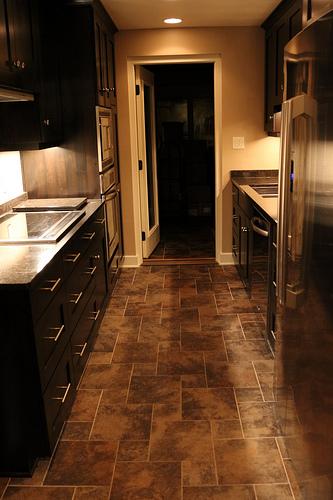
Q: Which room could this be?
A: It is a kitchen.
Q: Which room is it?
A: It is a kitchen.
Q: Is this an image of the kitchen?
A: Yes, it is showing the kitchen.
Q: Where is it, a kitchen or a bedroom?
A: It is a kitchen.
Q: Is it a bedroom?
A: No, it is a kitchen.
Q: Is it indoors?
A: Yes, it is indoors.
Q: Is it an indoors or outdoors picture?
A: It is indoors.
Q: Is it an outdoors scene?
A: No, it is indoors.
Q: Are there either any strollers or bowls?
A: No, there are no bowls or strollers.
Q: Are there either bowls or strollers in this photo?
A: No, there are no bowls or strollers.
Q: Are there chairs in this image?
A: No, there are no chairs.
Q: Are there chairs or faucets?
A: No, there are no chairs or faucets.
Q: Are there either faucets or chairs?
A: No, there are no chairs or faucets.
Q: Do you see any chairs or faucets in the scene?
A: No, there are no chairs or faucets.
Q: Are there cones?
A: No, there are no cones.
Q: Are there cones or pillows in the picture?
A: No, there are no cones or pillows.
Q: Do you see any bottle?
A: No, there are no bottles.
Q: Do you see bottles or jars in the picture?
A: No, there are no bottles or jars.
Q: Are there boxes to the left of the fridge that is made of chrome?
A: Yes, there are boxes to the left of the fridge.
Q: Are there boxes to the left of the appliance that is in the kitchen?
A: Yes, there are boxes to the left of the fridge.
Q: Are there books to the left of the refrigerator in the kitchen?
A: No, there are boxes to the left of the fridge.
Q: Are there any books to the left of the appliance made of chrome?
A: No, there are boxes to the left of the fridge.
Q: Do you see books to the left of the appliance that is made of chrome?
A: No, there are boxes to the left of the fridge.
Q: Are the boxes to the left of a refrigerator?
A: Yes, the boxes are to the left of a refrigerator.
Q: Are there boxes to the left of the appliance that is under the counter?
A: Yes, there are boxes to the left of the appliance.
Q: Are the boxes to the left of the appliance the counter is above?
A: Yes, the boxes are to the left of the appliance.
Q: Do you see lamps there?
A: No, there are no lamps.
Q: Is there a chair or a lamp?
A: No, there are no lamps or chairs.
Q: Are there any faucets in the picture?
A: No, there are no faucets.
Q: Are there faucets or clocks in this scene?
A: No, there are no faucets or clocks.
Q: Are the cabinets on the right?
A: No, the cabinets are on the left of the image.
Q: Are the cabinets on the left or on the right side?
A: The cabinets are on the left of the image.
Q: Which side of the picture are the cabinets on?
A: The cabinets are on the left of the image.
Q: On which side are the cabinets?
A: The cabinets are on the left of the image.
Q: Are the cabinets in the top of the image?
A: Yes, the cabinets are in the top of the image.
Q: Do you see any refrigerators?
A: Yes, there is a refrigerator.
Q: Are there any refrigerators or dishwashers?
A: Yes, there is a refrigerator.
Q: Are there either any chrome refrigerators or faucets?
A: Yes, there is a chrome refrigerator.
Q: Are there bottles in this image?
A: No, there are no bottles.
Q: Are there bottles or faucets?
A: No, there are no bottles or faucets.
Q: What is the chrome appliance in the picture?
A: The appliance is a refrigerator.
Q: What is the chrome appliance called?
A: The appliance is a refrigerator.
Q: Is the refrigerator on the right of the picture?
A: Yes, the refrigerator is on the right of the image.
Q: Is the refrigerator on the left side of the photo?
A: No, the refrigerator is on the right of the image.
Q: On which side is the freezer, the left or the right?
A: The freezer is on the right of the image.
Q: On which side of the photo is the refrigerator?
A: The refrigerator is on the right of the image.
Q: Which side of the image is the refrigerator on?
A: The refrigerator is on the right of the image.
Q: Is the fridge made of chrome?
A: Yes, the fridge is made of chrome.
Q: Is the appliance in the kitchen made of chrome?
A: Yes, the fridge is made of chrome.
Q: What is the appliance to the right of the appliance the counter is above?
A: The appliance is a refrigerator.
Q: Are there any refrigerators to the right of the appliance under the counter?
A: Yes, there is a refrigerator to the right of the appliance.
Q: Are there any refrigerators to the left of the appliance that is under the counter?
A: No, the refrigerator is to the right of the appliance.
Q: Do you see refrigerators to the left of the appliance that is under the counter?
A: No, the refrigerator is to the right of the appliance.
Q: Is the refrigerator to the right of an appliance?
A: Yes, the refrigerator is to the right of an appliance.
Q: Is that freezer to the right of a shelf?
A: No, the freezer is to the right of an appliance.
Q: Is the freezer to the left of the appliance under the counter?
A: No, the freezer is to the right of the appliance.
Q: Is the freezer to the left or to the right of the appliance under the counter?
A: The freezer is to the right of the appliance.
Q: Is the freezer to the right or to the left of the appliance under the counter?
A: The freezer is to the right of the appliance.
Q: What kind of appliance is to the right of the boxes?
A: The appliance is a refrigerator.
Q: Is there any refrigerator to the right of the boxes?
A: Yes, there is a refrigerator to the right of the boxes.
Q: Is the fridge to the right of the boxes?
A: Yes, the fridge is to the right of the boxes.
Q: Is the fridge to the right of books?
A: No, the fridge is to the right of the boxes.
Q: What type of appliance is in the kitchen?
A: The appliance is a refrigerator.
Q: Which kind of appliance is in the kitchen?
A: The appliance is a refrigerator.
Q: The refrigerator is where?
A: The refrigerator is in the kitchen.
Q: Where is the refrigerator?
A: The refrigerator is in the kitchen.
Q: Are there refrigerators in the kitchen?
A: Yes, there is a refrigerator in the kitchen.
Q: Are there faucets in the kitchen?
A: No, there is a refrigerator in the kitchen.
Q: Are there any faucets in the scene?
A: No, there are no faucets.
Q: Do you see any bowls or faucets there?
A: No, there are no faucets or bowls.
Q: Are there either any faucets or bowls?
A: No, there are no faucets or bowls.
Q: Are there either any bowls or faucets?
A: No, there are no faucets or bowls.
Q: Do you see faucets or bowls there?
A: No, there are no faucets or bowls.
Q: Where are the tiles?
A: The tiles are on the floor.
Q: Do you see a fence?
A: No, there are no fences.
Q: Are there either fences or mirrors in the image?
A: No, there are no fences or mirrors.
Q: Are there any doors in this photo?
A: Yes, there is a door.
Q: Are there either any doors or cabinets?
A: Yes, there is a door.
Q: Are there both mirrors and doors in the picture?
A: No, there is a door but no mirrors.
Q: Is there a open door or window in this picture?
A: Yes, there is an open door.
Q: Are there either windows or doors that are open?
A: Yes, the door is open.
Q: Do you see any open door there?
A: Yes, there is an open door.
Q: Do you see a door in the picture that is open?
A: Yes, there is a door that is open.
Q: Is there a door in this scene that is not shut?
A: Yes, there is a open door.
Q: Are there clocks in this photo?
A: No, there are no clocks.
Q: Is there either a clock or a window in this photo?
A: No, there are no clocks or windows.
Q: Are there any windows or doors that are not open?
A: No, there is a door but it is open.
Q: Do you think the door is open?
A: Yes, the door is open.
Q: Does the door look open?
A: Yes, the door is open.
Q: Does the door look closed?
A: No, the door is open.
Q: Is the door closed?
A: No, the door is open.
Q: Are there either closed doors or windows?
A: No, there is a door but it is open.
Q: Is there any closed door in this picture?
A: No, there is a door but it is open.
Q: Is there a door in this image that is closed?
A: No, there is a door but it is open.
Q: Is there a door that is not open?
A: No, there is a door but it is open.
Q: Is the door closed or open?
A: The door is open.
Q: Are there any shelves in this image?
A: No, there are no shelves.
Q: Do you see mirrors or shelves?
A: No, there are no shelves or mirrors.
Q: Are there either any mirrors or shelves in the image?
A: No, there are no shelves or mirrors.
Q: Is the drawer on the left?
A: Yes, the drawer is on the left of the image.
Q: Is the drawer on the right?
A: No, the drawer is on the left of the image.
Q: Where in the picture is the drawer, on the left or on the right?
A: The drawer is on the left of the image.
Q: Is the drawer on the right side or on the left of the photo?
A: The drawer is on the left of the image.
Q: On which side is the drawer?
A: The drawer is on the left of the image.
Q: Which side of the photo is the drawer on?
A: The drawer is on the left of the image.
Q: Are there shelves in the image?
A: No, there are no shelves.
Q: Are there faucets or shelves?
A: No, there are no shelves or faucets.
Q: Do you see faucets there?
A: No, there are no faucets.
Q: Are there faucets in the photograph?
A: No, there are no faucets.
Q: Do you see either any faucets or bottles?
A: No, there are no faucets or bottles.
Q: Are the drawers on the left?
A: Yes, the drawers are on the left of the image.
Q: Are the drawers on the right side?
A: No, the drawers are on the left of the image.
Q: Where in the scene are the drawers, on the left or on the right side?
A: The drawers are on the left of the image.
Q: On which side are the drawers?
A: The drawers are on the left of the image.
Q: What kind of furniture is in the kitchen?
A: The pieces of furniture are drawers.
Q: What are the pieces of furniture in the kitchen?
A: The pieces of furniture are drawers.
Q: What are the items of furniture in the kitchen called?
A: The pieces of furniture are drawers.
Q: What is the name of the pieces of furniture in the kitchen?
A: The pieces of furniture are drawers.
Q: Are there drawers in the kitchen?
A: Yes, there are drawers in the kitchen.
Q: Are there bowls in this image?
A: No, there are no bowls.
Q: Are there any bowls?
A: No, there are no bowls.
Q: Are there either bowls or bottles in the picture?
A: No, there are no bowls or bottles.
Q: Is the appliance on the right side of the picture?
A: Yes, the appliance is on the right of the image.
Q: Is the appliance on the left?
A: No, the appliance is on the right of the image.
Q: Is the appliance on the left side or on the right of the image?
A: The appliance is on the right of the image.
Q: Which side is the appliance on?
A: The appliance is on the right of the image.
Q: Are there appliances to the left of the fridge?
A: Yes, there is an appliance to the left of the fridge.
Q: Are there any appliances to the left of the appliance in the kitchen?
A: Yes, there is an appliance to the left of the fridge.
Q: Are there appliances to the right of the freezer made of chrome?
A: No, the appliance is to the left of the refrigerator.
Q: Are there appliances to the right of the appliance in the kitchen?
A: No, the appliance is to the left of the refrigerator.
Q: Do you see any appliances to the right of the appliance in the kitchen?
A: No, the appliance is to the left of the refrigerator.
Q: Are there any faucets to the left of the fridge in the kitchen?
A: No, there is an appliance to the left of the fridge.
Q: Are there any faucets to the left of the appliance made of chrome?
A: No, there is an appliance to the left of the fridge.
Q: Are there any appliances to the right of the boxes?
A: Yes, there is an appliance to the right of the boxes.